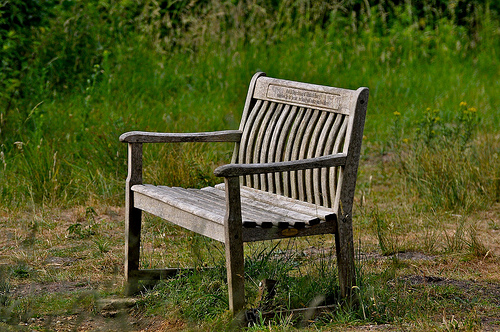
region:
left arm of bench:
[213, 152, 355, 175]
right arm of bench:
[112, 118, 247, 141]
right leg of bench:
[124, 135, 146, 283]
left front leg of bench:
[223, 171, 247, 330]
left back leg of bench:
[334, 184, 364, 316]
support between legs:
[243, 299, 358, 324]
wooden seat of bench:
[129, 179, 336, 239]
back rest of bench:
[230, 68, 372, 210]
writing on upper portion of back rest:
[262, 76, 349, 113]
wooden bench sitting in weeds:
[107, 65, 387, 323]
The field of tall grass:
[0, 0, 498, 330]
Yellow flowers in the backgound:
[383, 98, 480, 145]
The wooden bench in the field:
[115, 70, 371, 312]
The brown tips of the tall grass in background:
[152, 0, 464, 56]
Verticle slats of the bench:
[235, 68, 369, 204]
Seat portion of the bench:
[135, 171, 335, 245]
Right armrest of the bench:
[208, 153, 355, 181]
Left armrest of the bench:
[112, 120, 240, 150]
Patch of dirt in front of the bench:
[47, 297, 184, 329]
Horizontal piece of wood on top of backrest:
[250, 66, 373, 116]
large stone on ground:
[93, 291, 146, 313]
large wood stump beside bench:
[248, 277, 294, 322]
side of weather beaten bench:
[256, 215, 328, 230]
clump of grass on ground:
[55, 211, 107, 250]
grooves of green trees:
[67, 6, 276, 36]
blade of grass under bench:
[249, 232, 303, 268]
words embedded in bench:
[265, 81, 348, 111]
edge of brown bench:
[100, 122, 167, 157]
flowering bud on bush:
[74, 55, 102, 92]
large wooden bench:
[95, 76, 405, 275]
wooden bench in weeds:
[115, 66, 373, 314]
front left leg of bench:
[223, 166, 250, 315]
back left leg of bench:
[336, 156, 364, 319]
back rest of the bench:
[233, 69, 360, 209]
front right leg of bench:
[120, 131, 147, 297]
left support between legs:
[241, 299, 353, 329]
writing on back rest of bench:
[262, 80, 346, 111]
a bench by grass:
[118, 70, 370, 317]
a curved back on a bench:
[238, 98, 349, 207]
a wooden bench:
[118, 70, 370, 315]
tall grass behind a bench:
[1, 0, 499, 207]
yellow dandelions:
[391, 100, 482, 172]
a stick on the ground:
[101, 296, 137, 310]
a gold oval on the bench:
[278, 225, 295, 235]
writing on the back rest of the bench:
[275, 85, 340, 105]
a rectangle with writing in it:
[265, 80, 340, 105]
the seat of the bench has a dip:
[130, 178, 340, 230]